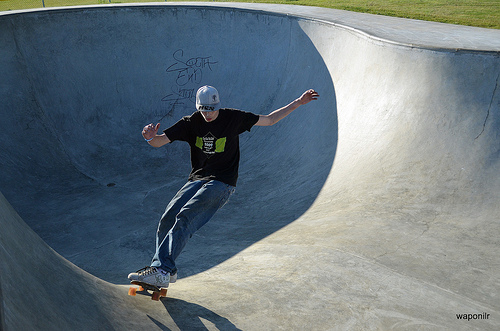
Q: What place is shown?
A: It is a park.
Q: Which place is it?
A: It is a park.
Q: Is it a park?
A: Yes, it is a park.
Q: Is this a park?
A: Yes, it is a park.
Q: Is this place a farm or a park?
A: It is a park.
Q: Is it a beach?
A: No, it is a park.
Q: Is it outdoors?
A: Yes, it is outdoors.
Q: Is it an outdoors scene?
A: Yes, it is outdoors.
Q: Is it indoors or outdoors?
A: It is outdoors.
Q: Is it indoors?
A: No, it is outdoors.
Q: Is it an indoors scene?
A: No, it is outdoors.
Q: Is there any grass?
A: Yes, there is grass.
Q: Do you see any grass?
A: Yes, there is grass.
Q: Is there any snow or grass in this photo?
A: Yes, there is grass.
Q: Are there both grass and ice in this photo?
A: No, there is grass but no ice.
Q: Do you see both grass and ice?
A: No, there is grass but no ice.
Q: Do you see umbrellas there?
A: No, there are no umbrellas.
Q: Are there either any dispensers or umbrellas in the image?
A: No, there are no umbrellas or dispensers.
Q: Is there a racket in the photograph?
A: No, there are no rackets.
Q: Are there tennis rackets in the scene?
A: No, there are no tennis rackets.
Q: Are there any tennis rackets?
A: No, there are no tennis rackets.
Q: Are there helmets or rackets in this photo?
A: No, there are no rackets or helmets.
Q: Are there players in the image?
A: No, there are no players.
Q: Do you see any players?
A: No, there are no players.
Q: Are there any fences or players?
A: No, there are no players or fences.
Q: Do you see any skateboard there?
A: Yes, there is a skateboard.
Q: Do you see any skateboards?
A: Yes, there is a skateboard.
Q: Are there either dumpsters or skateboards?
A: Yes, there is a skateboard.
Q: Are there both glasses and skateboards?
A: No, there is a skateboard but no glasses.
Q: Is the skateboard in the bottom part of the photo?
A: Yes, the skateboard is in the bottom of the image.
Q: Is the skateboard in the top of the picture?
A: No, the skateboard is in the bottom of the image.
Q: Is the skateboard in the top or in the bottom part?
A: The skateboard is in the bottom of the image.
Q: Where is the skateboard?
A: The skateboard is in the park.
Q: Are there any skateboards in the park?
A: Yes, there is a skateboard in the park.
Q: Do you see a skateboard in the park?
A: Yes, there is a skateboard in the park.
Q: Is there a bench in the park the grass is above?
A: No, there is a skateboard in the park.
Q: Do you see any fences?
A: No, there are no fences.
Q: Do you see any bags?
A: No, there are no bags.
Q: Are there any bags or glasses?
A: No, there are no bags or glasses.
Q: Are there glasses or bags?
A: No, there are no bags or glasses.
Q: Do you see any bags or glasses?
A: No, there are no bags or glasses.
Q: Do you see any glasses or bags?
A: No, there are no bags or glasses.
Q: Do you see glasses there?
A: No, there are no glasses.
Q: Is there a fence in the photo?
A: No, there are no fences.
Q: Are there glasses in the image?
A: No, there are no glasses.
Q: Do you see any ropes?
A: No, there are no ropes.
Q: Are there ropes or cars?
A: No, there are no ropes or cars.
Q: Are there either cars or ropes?
A: No, there are no ropes or cars.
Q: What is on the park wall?
A: The graffiti is on the wall.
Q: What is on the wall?
A: The graffiti is on the wall.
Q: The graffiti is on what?
A: The graffiti is on the wall.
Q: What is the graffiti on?
A: The graffiti is on the wall.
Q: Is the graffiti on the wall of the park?
A: Yes, the graffiti is on the wall.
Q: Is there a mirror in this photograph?
A: No, there are no mirrors.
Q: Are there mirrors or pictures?
A: No, there are no mirrors or pictures.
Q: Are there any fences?
A: No, there are no fences.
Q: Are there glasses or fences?
A: No, there are no fences or glasses.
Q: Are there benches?
A: No, there are no benches.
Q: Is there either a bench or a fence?
A: No, there are no benches or fences.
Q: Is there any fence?
A: No, there are no fences.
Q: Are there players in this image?
A: No, there are no players.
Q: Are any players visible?
A: No, there are no players.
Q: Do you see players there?
A: No, there are no players.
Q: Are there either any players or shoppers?
A: No, there are no players or shoppers.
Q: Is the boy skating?
A: Yes, the boy is skating.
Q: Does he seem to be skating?
A: Yes, the boy is skating.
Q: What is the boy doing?
A: The boy is skating.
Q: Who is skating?
A: The boy is skating.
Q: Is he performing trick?
A: No, the boy is skating.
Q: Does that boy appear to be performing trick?
A: No, the boy is skating.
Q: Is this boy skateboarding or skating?
A: The boy is skating.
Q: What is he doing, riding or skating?
A: The boy is skating.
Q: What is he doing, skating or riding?
A: The boy is skating.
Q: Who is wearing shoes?
A: The boy is wearing shoes.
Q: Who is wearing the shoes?
A: The boy is wearing shoes.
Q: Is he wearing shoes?
A: Yes, the boy is wearing shoes.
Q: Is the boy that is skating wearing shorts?
A: No, the boy is wearing shoes.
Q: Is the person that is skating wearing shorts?
A: No, the boy is wearing shoes.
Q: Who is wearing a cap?
A: The boy is wearing a cap.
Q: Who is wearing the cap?
A: The boy is wearing a cap.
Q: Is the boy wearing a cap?
A: Yes, the boy is wearing a cap.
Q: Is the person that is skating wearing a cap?
A: Yes, the boy is wearing a cap.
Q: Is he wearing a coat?
A: No, the boy is wearing a cap.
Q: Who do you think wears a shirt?
A: The boy wears a shirt.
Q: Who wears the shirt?
A: The boy wears a shirt.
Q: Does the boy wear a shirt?
A: Yes, the boy wears a shirt.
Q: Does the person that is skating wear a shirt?
A: Yes, the boy wears a shirt.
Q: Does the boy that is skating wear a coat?
A: No, the boy wears a shirt.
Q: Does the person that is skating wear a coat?
A: No, the boy wears a shirt.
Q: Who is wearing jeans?
A: The boy is wearing jeans.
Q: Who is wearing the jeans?
A: The boy is wearing jeans.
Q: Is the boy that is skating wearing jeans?
A: Yes, the boy is wearing jeans.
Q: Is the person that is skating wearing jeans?
A: Yes, the boy is wearing jeans.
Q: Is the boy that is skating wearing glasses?
A: No, the boy is wearing jeans.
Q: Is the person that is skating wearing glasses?
A: No, the boy is wearing jeans.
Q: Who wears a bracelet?
A: The boy wears a bracelet.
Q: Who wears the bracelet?
A: The boy wears a bracelet.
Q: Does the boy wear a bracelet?
A: Yes, the boy wears a bracelet.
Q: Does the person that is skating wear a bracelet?
A: Yes, the boy wears a bracelet.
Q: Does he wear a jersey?
A: No, the boy wears a bracelet.